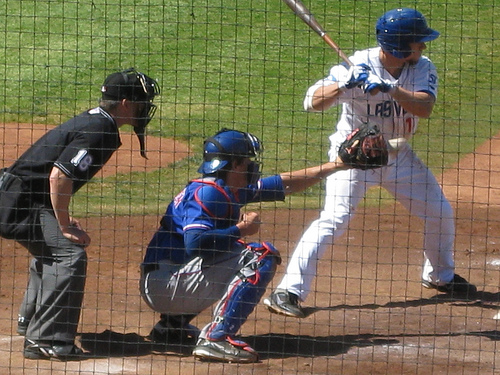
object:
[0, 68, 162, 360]
umpire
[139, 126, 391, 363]
catcher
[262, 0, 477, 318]
player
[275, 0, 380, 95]
bat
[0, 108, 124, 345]
uniform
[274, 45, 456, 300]
uniform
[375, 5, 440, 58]
helmet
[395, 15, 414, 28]
blue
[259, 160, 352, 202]
arm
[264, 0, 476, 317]
baseball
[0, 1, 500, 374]
fence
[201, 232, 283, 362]
knee guard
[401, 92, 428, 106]
skinned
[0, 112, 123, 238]
t shirt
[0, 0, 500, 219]
grass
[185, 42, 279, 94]
ground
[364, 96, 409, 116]
las vegas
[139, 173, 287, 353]
uniform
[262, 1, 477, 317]
game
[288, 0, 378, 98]
hit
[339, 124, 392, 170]
receive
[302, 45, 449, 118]
technique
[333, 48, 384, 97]
hitting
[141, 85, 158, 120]
watching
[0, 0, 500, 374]
baseball field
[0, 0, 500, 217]
background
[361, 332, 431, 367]
homeplate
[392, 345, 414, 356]
seen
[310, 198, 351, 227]
legs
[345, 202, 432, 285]
open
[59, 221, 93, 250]
hand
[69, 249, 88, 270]
knee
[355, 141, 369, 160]
black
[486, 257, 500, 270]
white dust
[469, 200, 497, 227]
dirt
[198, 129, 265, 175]
hat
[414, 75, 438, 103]
short sleeved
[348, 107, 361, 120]
white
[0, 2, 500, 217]
field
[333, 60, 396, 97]
two gloves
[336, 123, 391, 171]
mitt